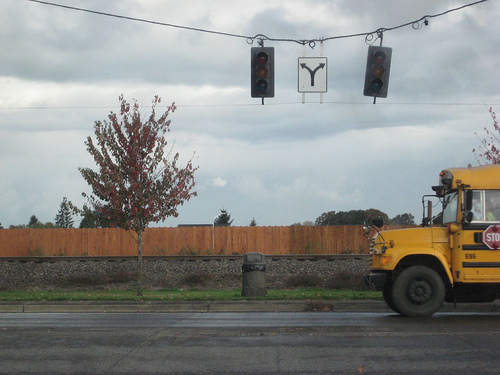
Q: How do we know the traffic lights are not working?
A: They are not lit.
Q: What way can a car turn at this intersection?
A: Left and right.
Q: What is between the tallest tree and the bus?
A: A trash can.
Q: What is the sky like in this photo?
A: Overcast.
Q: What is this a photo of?
A: A rural street sign.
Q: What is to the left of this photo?
A: A yellow school bus.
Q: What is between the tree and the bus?
A: A trash can.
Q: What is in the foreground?
A: The street.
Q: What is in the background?
A: Stormy sky.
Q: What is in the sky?
A: White clouds.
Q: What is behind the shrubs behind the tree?
A: Wooden fence.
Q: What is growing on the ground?
A: Green grass.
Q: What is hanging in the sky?
A: Street lights and directions.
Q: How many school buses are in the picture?
A: 1.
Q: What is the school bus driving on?
A: The road.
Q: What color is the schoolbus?
A: Yellow.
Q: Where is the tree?
A: To the left of the bus.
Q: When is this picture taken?
A: During the day.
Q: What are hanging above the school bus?
A: Traffic lights.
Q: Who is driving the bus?
A: A bus driver.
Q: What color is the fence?
A: Brown.